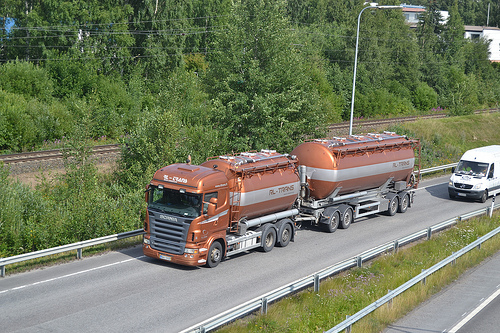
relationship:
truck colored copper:
[144, 130, 425, 268] [201, 169, 223, 184]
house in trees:
[364, 0, 498, 70] [1, 7, 498, 117]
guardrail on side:
[2, 228, 142, 277] [14, 166, 149, 251]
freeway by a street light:
[1, 162, 499, 333] [348, 3, 403, 136]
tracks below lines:
[1, 105, 499, 170] [4, 16, 492, 60]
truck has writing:
[144, 130, 425, 268] [267, 180, 297, 196]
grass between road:
[310, 291, 339, 322] [200, 163, 499, 332]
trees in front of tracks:
[6, 139, 146, 230] [1, 105, 499, 170]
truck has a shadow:
[144, 130, 425, 268] [114, 208, 383, 272]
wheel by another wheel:
[278, 220, 291, 245] [261, 225, 276, 253]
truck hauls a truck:
[144, 130, 425, 268] [144, 130, 425, 268]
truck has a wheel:
[144, 130, 425, 268] [261, 225, 276, 253]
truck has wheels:
[144, 130, 425, 268] [304, 189, 416, 233]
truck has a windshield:
[144, 130, 425, 268] [146, 184, 202, 221]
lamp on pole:
[348, 3, 403, 136] [349, 7, 371, 138]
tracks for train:
[1, 105, 499, 170] [3, 143, 122, 166]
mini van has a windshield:
[447, 139, 499, 204] [453, 160, 490, 179]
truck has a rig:
[144, 130, 425, 268] [292, 132, 423, 233]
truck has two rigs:
[144, 130, 425, 268] [203, 130, 423, 268]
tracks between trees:
[1, 105, 499, 170] [1, 7, 498, 117]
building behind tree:
[365, 6, 498, 68] [439, 10, 470, 70]